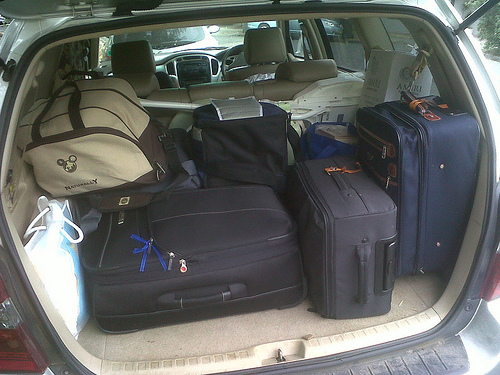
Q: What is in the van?
A: Luggage.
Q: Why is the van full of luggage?
A: Going on a trip.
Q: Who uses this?
A: Man.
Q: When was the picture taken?
A: Daytime.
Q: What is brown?
A: Duffle Bag.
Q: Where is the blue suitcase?
A: On the right.